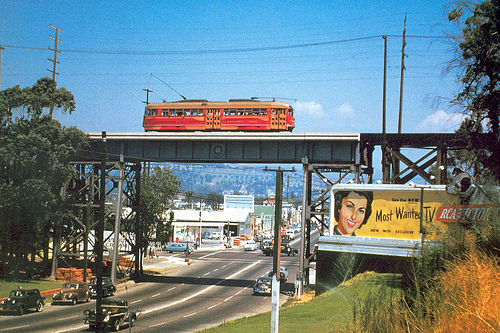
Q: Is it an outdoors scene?
A: Yes, it is outdoors.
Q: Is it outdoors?
A: Yes, it is outdoors.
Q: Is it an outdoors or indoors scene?
A: It is outdoors.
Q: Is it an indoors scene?
A: No, it is outdoors.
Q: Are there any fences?
A: No, there are no fences.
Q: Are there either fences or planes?
A: No, there are no fences or planes.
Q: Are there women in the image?
A: Yes, there is a woman.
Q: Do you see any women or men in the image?
A: Yes, there is a woman.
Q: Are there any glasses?
A: No, there are no glasses.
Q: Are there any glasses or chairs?
A: No, there are no glasses or chairs.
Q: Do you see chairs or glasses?
A: No, there are no glasses or chairs.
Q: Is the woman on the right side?
A: Yes, the woman is on the right of the image.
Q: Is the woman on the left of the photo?
A: No, the woman is on the right of the image.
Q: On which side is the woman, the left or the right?
A: The woman is on the right of the image.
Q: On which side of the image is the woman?
A: The woman is on the right of the image.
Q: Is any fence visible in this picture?
A: No, there are no fences.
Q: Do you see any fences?
A: No, there are no fences.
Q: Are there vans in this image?
A: No, there are no vans.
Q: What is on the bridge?
A: The car is on the bridge.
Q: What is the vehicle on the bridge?
A: The vehicle is a car.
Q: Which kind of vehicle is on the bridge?
A: The vehicle is a car.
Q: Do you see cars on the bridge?
A: Yes, there is a car on the bridge.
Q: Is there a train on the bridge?
A: No, there is a car on the bridge.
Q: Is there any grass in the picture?
A: Yes, there is grass.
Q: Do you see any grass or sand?
A: Yes, there is grass.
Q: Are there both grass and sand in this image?
A: No, there is grass but no sand.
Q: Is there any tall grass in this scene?
A: Yes, there is tall grass.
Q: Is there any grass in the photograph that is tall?
A: Yes, there is grass that is tall.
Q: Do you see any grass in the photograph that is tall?
A: Yes, there is grass that is tall.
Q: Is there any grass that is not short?
A: Yes, there is tall grass.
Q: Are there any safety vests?
A: No, there are no safety vests.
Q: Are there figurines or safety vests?
A: No, there are no safety vests or figurines.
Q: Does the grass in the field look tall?
A: Yes, the grass is tall.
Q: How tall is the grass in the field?
A: The grass is tall.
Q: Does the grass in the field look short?
A: No, the grass is tall.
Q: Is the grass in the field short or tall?
A: The grass is tall.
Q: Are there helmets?
A: No, there are no helmets.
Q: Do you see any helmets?
A: No, there are no helmets.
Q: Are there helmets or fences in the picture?
A: No, there are no helmets or fences.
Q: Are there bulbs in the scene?
A: No, there are no bulbs.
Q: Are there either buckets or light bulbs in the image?
A: No, there are no light bulbs or buckets.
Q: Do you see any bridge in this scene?
A: Yes, there is a bridge.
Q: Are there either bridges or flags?
A: Yes, there is a bridge.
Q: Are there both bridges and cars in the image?
A: Yes, there are both a bridge and a car.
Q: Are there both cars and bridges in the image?
A: Yes, there are both a bridge and a car.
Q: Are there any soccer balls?
A: No, there are no soccer balls.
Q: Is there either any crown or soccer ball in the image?
A: No, there are no soccer balls or crowns.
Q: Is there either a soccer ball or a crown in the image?
A: No, there are no soccer balls or crowns.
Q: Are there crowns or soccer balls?
A: No, there are no soccer balls or crowns.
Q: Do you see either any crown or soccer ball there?
A: No, there are no soccer balls or crowns.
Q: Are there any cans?
A: No, there are no cans.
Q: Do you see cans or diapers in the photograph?
A: No, there are no cans or diapers.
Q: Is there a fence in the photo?
A: No, there are no fences.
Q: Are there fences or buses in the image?
A: No, there are no fences or buses.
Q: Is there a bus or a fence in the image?
A: No, there are no fences or buses.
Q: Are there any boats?
A: No, there are no boats.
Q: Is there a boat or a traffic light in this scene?
A: No, there are no boats or traffic lights.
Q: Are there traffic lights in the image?
A: No, there are no traffic lights.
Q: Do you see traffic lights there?
A: No, there are no traffic lights.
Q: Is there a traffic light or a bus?
A: No, there are no traffic lights or buses.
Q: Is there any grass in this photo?
A: Yes, there is grass.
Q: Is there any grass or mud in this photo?
A: Yes, there is grass.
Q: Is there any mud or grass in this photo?
A: Yes, there is grass.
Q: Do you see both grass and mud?
A: No, there is grass but no mud.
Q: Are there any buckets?
A: No, there are no buckets.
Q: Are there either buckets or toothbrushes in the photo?
A: No, there are no buckets or toothbrushes.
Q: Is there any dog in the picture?
A: Yes, there is a dog.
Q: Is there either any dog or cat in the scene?
A: Yes, there is a dog.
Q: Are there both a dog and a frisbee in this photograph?
A: No, there is a dog but no frisbees.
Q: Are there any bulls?
A: No, there are no bulls.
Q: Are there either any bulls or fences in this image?
A: No, there are no bulls or fences.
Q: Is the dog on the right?
A: Yes, the dog is on the right of the image.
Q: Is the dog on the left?
A: No, the dog is on the right of the image.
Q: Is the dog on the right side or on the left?
A: The dog is on the right of the image.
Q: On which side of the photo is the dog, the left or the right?
A: The dog is on the right of the image.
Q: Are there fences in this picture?
A: No, there are no fences.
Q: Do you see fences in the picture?
A: No, there are no fences.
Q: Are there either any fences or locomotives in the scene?
A: No, there are no fences or locomotives.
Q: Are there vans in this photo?
A: No, there are no vans.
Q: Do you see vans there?
A: No, there are no vans.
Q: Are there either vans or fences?
A: No, there are no vans or fences.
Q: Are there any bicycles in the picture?
A: No, there are no bicycles.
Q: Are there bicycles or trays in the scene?
A: No, there are no bicycles or trays.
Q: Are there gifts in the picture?
A: No, there are no gifts.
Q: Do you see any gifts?
A: No, there are no gifts.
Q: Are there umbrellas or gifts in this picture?
A: No, there are no gifts or umbrellas.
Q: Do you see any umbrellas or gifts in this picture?
A: No, there are no gifts or umbrellas.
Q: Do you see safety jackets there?
A: No, there are no safety jackets.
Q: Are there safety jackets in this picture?
A: No, there are no safety jackets.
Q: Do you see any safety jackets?
A: No, there are no safety jackets.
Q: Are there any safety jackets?
A: No, there are no safety jackets.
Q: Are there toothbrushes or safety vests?
A: No, there are no safety vests or toothbrushes.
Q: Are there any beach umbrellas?
A: No, there are no beach umbrellas.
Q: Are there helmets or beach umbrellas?
A: No, there are no beach umbrellas or helmets.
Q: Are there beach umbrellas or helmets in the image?
A: No, there are no beach umbrellas or helmets.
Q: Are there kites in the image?
A: No, there are no kites.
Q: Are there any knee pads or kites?
A: No, there are no kites or knee pads.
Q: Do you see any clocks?
A: No, there are no clocks.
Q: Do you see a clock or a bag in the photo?
A: No, there are no clocks or bags.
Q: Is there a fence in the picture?
A: No, there are no fences.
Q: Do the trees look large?
A: Yes, the trees are large.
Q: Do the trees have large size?
A: Yes, the trees are large.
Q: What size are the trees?
A: The trees are large.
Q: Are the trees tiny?
A: No, the trees are large.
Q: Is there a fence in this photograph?
A: No, there are no fences.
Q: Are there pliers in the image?
A: No, there are no pliers.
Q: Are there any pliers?
A: No, there are no pliers.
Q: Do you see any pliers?
A: No, there are no pliers.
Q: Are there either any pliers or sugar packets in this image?
A: No, there are no pliers or sugar packets.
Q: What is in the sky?
A: The clouds are in the sky.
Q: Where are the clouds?
A: The clouds are in the sky.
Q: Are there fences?
A: No, there are no fences.